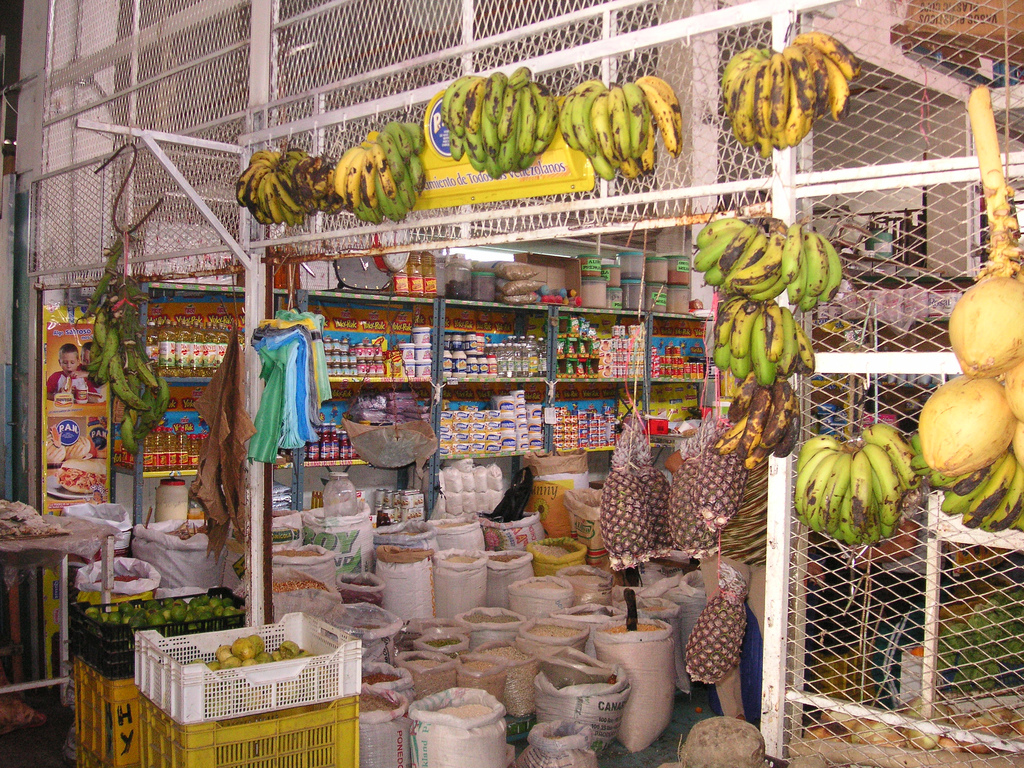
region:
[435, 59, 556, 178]
bunch of bananas hang on a mesh wall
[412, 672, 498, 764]
a sack of grain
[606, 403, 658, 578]
fresh pineapples hang on hooks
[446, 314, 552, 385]
shelf of products in a jar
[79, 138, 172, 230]
large s shaped hook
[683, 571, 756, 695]
fresh pineapple hanging from a hook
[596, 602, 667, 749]
white sack of grain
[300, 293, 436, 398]
shelf with canned goods on display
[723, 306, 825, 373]
A BUNCH OF BANANAS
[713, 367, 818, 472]
A BUNCH OF BANANAS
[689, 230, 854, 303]
A BUNCH OF BANANAS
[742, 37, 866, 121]
A BUNCH OF BANANAS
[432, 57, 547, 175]
A BUNCH OF BANANAS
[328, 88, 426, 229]
A BUNCH OF BANANAS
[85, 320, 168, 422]
A BUNCH OF BANANAS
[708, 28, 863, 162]
Yellow and brown banana bunch.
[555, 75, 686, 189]
Yellow green and brown banana bunch.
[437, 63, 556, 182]
Yellow green and brown banana bunch.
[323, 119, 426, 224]
Yellow green and brown banana bunch.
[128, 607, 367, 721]
Yellow fruit inside white crate.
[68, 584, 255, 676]
Green fruit inside black crate.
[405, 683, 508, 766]
Beige spice inside a white sack.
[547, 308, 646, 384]
Cans on top of a shelf.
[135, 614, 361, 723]
rectangular shaped white crate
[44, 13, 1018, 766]
white fencing around the market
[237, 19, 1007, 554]
bananas hanging on the white fencing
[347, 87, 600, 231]
yellow sign on the fencing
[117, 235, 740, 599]
shelves in the market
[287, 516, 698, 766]
full plastic bags on the floor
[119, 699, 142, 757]
black letters on yellow crate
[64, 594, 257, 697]
black crate with green fruit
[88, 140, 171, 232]
large S hook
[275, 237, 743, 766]
doorway to the market